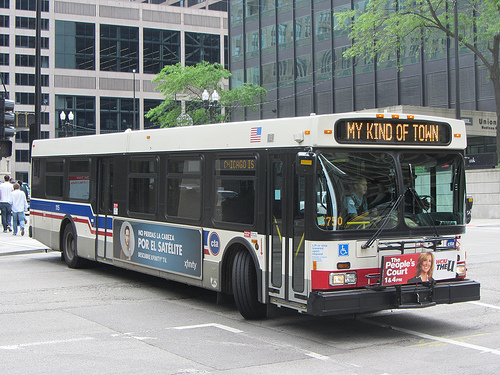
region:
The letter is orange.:
[342, 119, 357, 143]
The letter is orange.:
[353, 122, 365, 142]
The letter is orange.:
[361, 117, 375, 141]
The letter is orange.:
[371, 117, 380, 145]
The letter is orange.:
[376, 119, 388, 148]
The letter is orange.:
[383, 118, 394, 145]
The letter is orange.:
[393, 115, 403, 142]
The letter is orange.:
[401, 121, 412, 146]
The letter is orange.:
[409, 120, 419, 145]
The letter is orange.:
[418, 123, 426, 145]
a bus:
[28, 110, 475, 300]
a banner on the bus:
[379, 254, 439, 282]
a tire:
[232, 268, 256, 310]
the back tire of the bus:
[59, 225, 81, 260]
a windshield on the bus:
[327, 148, 460, 218]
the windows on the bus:
[162, 164, 255, 223]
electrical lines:
[266, 58, 325, 103]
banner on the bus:
[110, 218, 202, 280]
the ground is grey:
[10, 280, 115, 344]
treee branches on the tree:
[422, 15, 475, 55]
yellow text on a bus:
[337, 112, 452, 147]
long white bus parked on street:
[31, 113, 479, 325]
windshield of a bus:
[310, 143, 470, 243]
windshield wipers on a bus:
[365, 180, 437, 255]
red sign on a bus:
[379, 252, 446, 297]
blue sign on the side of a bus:
[101, 203, 222, 281]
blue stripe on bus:
[26, 195, 120, 260]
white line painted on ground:
[356, 308, 497, 371]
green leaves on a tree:
[335, 0, 498, 70]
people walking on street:
[0, 169, 34, 236]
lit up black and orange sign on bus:
[328, 112, 462, 152]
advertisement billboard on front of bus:
[366, 245, 441, 294]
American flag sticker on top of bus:
[243, 122, 268, 147]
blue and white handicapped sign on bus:
[336, 242, 350, 257]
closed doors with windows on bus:
[256, 143, 310, 315]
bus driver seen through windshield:
[339, 167, 390, 229]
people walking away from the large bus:
[2, 155, 38, 259]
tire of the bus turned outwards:
[207, 229, 272, 332]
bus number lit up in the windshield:
[316, 205, 350, 240]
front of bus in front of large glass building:
[275, 53, 499, 348]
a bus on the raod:
[123, 5, 489, 291]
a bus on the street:
[229, 79, 499, 336]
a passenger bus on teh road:
[149, 53, 439, 365]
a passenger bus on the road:
[97, 80, 494, 373]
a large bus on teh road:
[172, 61, 499, 358]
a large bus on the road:
[84, 76, 410, 362]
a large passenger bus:
[51, 91, 491, 298]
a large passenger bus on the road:
[78, 82, 468, 257]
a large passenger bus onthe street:
[136, 36, 493, 346]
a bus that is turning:
[117, 129, 470, 373]